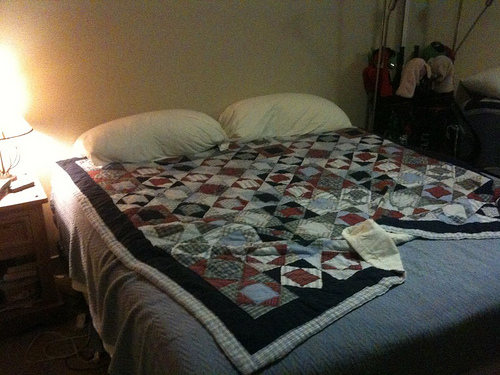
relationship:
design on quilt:
[197, 250, 243, 287] [57, 125, 500, 375]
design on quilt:
[259, 197, 318, 229] [62, 76, 499, 366]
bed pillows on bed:
[67, 85, 375, 170] [75, 197, 497, 374]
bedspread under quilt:
[49, 166, 500, 375] [57, 125, 500, 375]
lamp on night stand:
[0, 102, 35, 176] [3, 170, 78, 341]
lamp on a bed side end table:
[3, 48, 48, 198] [0, 175, 64, 325]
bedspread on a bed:
[49, 166, 500, 375] [47, 117, 498, 373]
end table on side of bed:
[0, 172, 68, 327] [46, 89, 496, 373]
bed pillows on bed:
[71, 108, 231, 167] [47, 117, 498, 373]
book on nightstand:
[8, 172, 34, 193] [0, 168, 58, 335]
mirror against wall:
[422, 7, 498, 159] [381, 3, 498, 174]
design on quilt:
[238, 245, 305, 305] [179, 218, 339, 271]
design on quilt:
[321, 250, 362, 272] [57, 125, 500, 375]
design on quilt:
[245, 260, 312, 304] [148, 269, 334, 366]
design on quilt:
[229, 206, 271, 226] [57, 125, 500, 375]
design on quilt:
[340, 185, 371, 207] [57, 125, 500, 375]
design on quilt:
[112, 187, 163, 210] [57, 125, 500, 375]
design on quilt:
[203, 179, 252, 215] [57, 125, 500, 375]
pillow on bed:
[218, 92, 354, 140] [46, 89, 496, 373]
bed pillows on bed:
[71, 108, 231, 167] [46, 89, 496, 373]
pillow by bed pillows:
[218, 92, 354, 140] [71, 108, 231, 167]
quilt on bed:
[57, 125, 500, 375] [46, 89, 496, 373]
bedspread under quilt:
[56, 138, 496, 373] [57, 125, 500, 375]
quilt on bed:
[164, 160, 481, 331] [304, 247, 499, 368]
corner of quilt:
[229, 346, 269, 371] [57, 125, 500, 375]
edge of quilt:
[176, 295, 215, 342] [57, 125, 500, 375]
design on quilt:
[222, 265, 302, 320] [57, 125, 500, 375]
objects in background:
[366, 35, 463, 105] [340, 32, 495, 160]